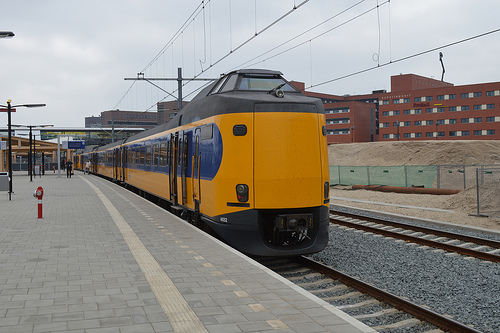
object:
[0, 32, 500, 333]
train station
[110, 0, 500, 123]
wires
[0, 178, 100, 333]
platform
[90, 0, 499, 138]
powerlines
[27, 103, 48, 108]
light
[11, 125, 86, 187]
station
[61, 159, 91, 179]
people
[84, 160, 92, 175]
man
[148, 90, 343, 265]
train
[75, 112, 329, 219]
yellow train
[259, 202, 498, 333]
gray gravel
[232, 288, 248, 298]
yellow line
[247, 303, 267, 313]
yellow line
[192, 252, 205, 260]
yellow line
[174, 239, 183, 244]
yellow line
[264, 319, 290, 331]
yellow line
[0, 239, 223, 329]
ground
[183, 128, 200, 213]
door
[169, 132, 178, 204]
door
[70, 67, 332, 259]
train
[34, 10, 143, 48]
sky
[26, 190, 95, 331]
road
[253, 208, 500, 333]
railway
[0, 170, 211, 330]
tile road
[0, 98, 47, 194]
poles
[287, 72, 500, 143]
brown building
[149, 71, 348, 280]
train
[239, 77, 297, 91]
windshield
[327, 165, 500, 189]
fence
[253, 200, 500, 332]
track